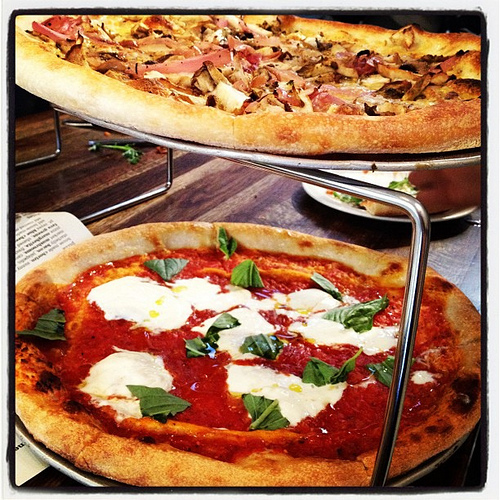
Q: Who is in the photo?
A: No one.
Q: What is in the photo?
A: Pizza.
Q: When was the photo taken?
A: Daytime.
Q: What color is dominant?
A: Red.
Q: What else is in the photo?
A: Table.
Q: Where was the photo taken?
A: In a restaurant.